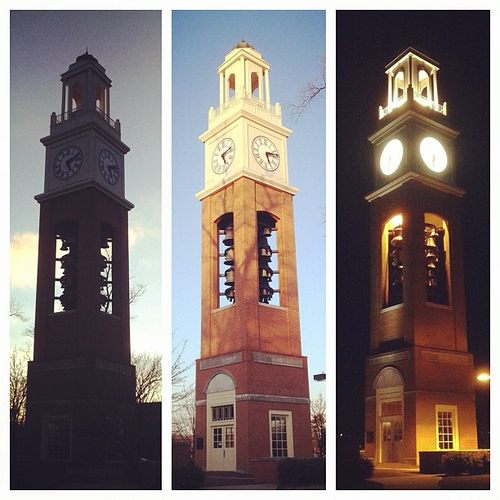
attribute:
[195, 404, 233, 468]
door — white